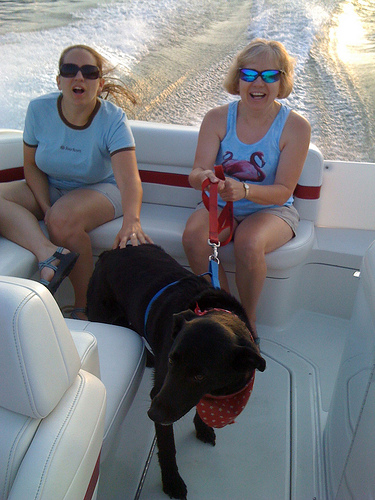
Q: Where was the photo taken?
A: It was taken at the ocean.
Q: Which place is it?
A: It is an ocean.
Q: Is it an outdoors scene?
A: Yes, it is outdoors.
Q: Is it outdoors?
A: Yes, it is outdoors.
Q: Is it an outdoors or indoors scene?
A: It is outdoors.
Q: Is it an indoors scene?
A: No, it is outdoors.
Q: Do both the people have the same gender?
A: Yes, all the people are female.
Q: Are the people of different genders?
A: No, all the people are female.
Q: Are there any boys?
A: No, there are no boys.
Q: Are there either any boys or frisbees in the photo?
A: No, there are no boys or frisbees.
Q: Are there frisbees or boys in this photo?
A: No, there are no boys or frisbees.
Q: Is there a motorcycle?
A: No, there are no motorcycles.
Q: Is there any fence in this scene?
A: No, there are no fences.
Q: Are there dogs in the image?
A: Yes, there is a dog.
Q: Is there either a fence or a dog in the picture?
A: Yes, there is a dog.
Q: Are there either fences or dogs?
A: Yes, there is a dog.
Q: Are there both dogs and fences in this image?
A: No, there is a dog but no fences.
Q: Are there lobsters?
A: No, there are no lobsters.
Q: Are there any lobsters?
A: No, there are no lobsters.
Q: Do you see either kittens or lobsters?
A: No, there are no lobsters or kittens.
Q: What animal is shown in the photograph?
A: The animal is a dog.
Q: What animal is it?
A: The animal is a dog.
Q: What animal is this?
A: This is a dog.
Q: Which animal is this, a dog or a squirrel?
A: This is a dog.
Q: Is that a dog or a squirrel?
A: That is a dog.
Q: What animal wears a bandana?
A: The dog wears a bandana.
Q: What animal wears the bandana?
A: The dog wears a bandana.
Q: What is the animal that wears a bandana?
A: The animal is a dog.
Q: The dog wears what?
A: The dog wears a bandana.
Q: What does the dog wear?
A: The dog wears a bandana.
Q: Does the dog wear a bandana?
A: Yes, the dog wears a bandana.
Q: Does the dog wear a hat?
A: No, the dog wears a bandana.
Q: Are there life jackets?
A: No, there are no life jackets.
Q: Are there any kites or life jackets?
A: No, there are no life jackets or kites.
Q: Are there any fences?
A: No, there are no fences.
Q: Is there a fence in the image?
A: No, there are no fences.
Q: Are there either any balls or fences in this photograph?
A: No, there are no fences or balls.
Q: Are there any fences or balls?
A: No, there are no fences or balls.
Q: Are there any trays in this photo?
A: No, there are no trays.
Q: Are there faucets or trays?
A: No, there are no trays or faucets.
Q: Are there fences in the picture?
A: No, there are no fences.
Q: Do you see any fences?
A: No, there are no fences.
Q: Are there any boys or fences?
A: No, there are no boys or fences.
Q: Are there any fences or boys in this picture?
A: No, there are no boys or fences.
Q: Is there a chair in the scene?
A: Yes, there is a chair.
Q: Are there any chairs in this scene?
A: Yes, there is a chair.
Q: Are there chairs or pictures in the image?
A: Yes, there is a chair.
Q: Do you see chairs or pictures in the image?
A: Yes, there is a chair.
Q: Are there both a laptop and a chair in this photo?
A: No, there is a chair but no laptops.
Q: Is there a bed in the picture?
A: No, there are no beds.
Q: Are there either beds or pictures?
A: No, there are no beds or pictures.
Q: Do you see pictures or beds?
A: No, there are no beds or pictures.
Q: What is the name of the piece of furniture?
A: The piece of furniture is a chair.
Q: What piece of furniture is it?
A: The piece of furniture is a chair.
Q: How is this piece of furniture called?
A: This is a chair.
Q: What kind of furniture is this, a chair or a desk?
A: This is a chair.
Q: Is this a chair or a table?
A: This is a chair.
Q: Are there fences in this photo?
A: No, there are no fences.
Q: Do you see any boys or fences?
A: No, there are no fences or boys.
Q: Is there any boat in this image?
A: Yes, there is a boat.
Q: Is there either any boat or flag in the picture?
A: Yes, there is a boat.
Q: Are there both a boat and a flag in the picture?
A: No, there is a boat but no flags.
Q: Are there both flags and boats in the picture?
A: No, there is a boat but no flags.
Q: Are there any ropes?
A: No, there are no ropes.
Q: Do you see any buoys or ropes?
A: No, there are no ropes or buoys.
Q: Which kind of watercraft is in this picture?
A: The watercraft is a boat.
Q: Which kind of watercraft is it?
A: The watercraft is a boat.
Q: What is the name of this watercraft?
A: This is a boat.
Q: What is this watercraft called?
A: This is a boat.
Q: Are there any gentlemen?
A: No, there are no gentlemen.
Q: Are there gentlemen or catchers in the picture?
A: No, there are no gentlemen or catchers.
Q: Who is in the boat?
A: The lady is in the boat.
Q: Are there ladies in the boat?
A: Yes, there is a lady in the boat.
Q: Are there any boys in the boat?
A: No, there is a lady in the boat.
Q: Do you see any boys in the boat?
A: No, there is a lady in the boat.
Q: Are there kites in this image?
A: No, there are no kites.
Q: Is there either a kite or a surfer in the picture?
A: No, there are no kites or surfers.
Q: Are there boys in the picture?
A: No, there are no boys.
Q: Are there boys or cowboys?
A: No, there are no boys or cowboys.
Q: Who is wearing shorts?
A: The lady is wearing shorts.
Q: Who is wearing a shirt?
A: The lady is wearing a shirt.